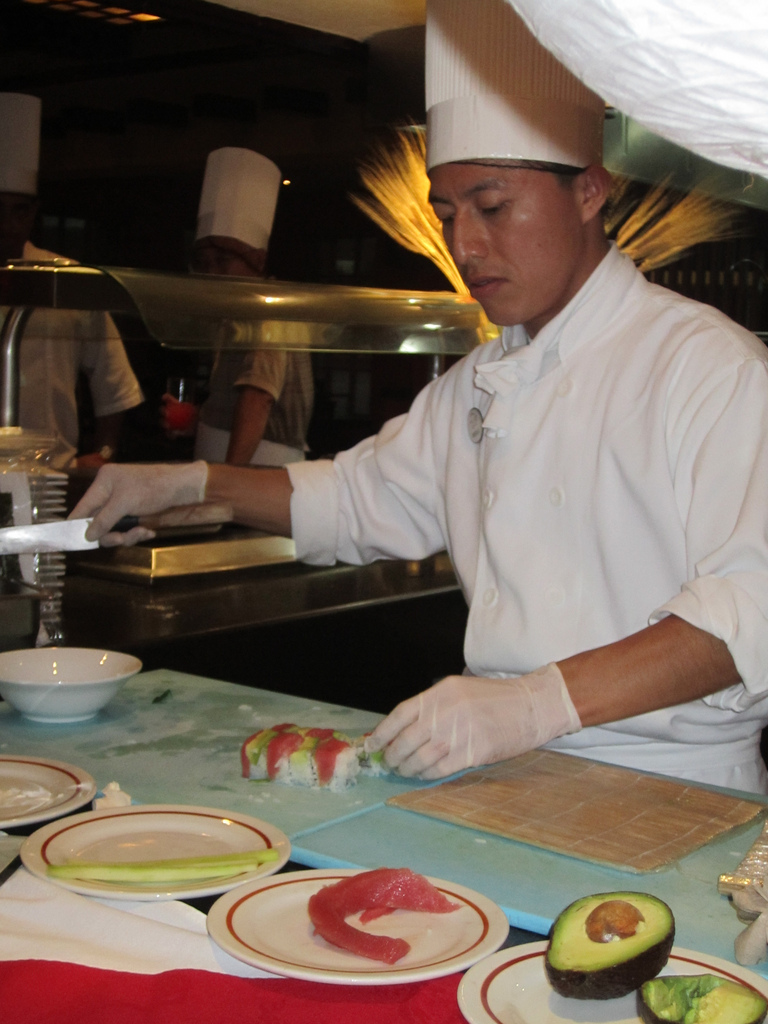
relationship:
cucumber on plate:
[52, 851, 285, 881] [20, 804, 292, 901]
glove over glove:
[352, 660, 585, 764] [366, 662, 585, 782]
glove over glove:
[68, 458, 222, 537] [69, 460, 211, 547]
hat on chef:
[424, 0, 606, 172] [73, 1, 764, 805]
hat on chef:
[424, 1, 606, 168] [73, 1, 764, 805]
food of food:
[310, 866, 468, 964] [316, 861, 468, 960]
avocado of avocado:
[544, 890, 675, 1000] [544, 890, 675, 1000]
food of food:
[638, 974, 768, 1024] [638, 973, 718, 1012]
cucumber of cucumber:
[48, 849, 280, 881] [48, 849, 280, 881]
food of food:
[241, 723, 393, 792] [234, 726, 363, 780]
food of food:
[241, 723, 393, 792] [313, 731, 346, 793]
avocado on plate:
[534, 890, 672, 1005] [454, 935, 743, 1020]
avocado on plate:
[544, 890, 675, 1000] [458, 935, 738, 1011]